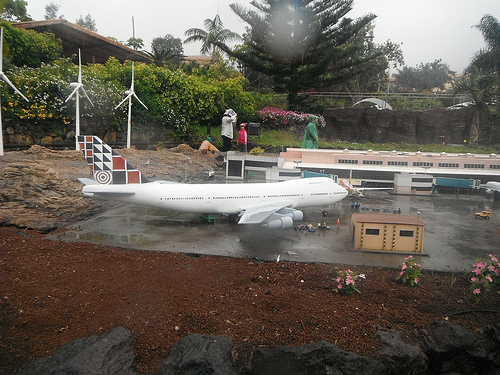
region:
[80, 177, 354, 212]
the body of the plane is white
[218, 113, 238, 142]
the man is wearing a white jacket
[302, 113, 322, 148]
the man is dressed in green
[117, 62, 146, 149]
the wind turbine is white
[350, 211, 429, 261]
the shed is brown in color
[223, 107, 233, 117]
the man is wearing a white hat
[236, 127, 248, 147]
the boy is wearing a red jacket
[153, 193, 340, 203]
the plane has a row of windows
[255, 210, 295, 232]
the engine is under the wing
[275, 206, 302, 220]
the engine is under the wing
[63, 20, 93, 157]
this is a wind mill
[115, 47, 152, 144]
this is a wind mill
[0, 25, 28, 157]
this is a wind mill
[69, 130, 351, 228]
this is a plane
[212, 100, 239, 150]
this is a person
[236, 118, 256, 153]
this is a person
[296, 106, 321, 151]
this is a person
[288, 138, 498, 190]
this is a building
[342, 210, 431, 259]
this is a building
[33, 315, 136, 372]
this is a rock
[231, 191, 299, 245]
right wing of plane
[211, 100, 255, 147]
guy in beige coat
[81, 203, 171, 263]
wet asphalt under plane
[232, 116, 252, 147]
man in red shirt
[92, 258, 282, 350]
wet dirt by asphalt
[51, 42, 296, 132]
big green bushes in back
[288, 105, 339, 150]
guy in big green suit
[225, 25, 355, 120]
dark evergreen tree in back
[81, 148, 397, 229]
long white plane on asphalt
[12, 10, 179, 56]
brown top of house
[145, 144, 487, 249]
miniature model of airport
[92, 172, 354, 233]
model of white plane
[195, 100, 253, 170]
people heind model airport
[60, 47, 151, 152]
two white wind turbines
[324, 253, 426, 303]
pink flowers in mulch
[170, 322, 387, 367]
rock tops in front of mulch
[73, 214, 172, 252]
puddle of wet cement surface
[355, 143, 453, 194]
model of airport terminal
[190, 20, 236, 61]
leaves of palm tree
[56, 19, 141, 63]
flat roof of building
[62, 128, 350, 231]
a large model airplane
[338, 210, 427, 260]
small light brown model building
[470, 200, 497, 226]
small model car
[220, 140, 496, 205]
large model airport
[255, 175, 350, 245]
small figures near model airplane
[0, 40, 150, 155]
small white wind turbines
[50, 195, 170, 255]
water forming puddles on paved ground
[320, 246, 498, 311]
plants with pink flowers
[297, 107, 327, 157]
person wearing a green poncho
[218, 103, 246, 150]
person using object to protect their head